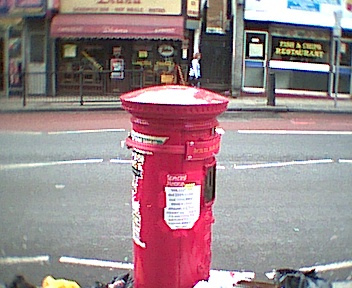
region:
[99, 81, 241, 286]
the hydrant on the street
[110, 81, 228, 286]
the hydrant is red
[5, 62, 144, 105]
the fence across the street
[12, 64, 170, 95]
the fence is black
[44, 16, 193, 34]
the awning of the store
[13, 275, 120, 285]
garbage on the street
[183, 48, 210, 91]
the person across the street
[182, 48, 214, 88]
the person is walking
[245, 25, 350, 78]
restaurant across the street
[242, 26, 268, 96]
door of the restaurant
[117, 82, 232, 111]
red shiny circular piece of metal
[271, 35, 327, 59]
one yellow lettered FISH & CHIPS RESTAURANT sign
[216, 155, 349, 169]
section of broken white line in street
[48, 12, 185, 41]
dark red canvas shop awning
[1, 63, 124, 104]
section of black metal fencing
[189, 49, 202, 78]
one woman wearing light colored jacket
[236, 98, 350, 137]
section of red colored pavement along curb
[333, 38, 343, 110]
one thin gray metal pole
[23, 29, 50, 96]
one white rectangular storm door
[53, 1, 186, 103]
one storefront behind metal fence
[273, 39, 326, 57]
sign for a specialty restaurant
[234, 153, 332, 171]
dividing line on a British road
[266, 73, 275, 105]
post on the opposite sidewalk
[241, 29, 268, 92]
the door of the restaurant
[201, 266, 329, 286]
debris around the pink object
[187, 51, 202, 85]
a woman standing on the sidewalk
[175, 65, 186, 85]
a pole leaning against a wall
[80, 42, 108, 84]
the window of a commercial building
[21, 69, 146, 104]
a rack for bicycles on the sidewalk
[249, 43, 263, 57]
sign on a restaurant door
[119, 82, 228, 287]
the street post is red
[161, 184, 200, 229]
a white sticker on the post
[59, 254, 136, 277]
white line on the asphalt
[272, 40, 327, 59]
the business name on the window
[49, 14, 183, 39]
red awning on the building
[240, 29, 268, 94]
business door is closed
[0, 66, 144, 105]
black metal fencing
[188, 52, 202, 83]
a person walking on the street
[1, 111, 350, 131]
side of the road is red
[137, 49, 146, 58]
sticker on the window